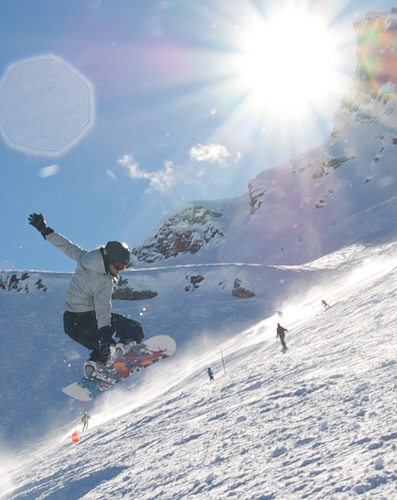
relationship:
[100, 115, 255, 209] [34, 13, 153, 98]
clouds in sky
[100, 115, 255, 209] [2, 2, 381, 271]
clouds in sky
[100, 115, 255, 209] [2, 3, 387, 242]
clouds in sky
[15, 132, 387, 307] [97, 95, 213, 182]
mountain with clouds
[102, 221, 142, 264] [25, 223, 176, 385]
helmet on snowboarder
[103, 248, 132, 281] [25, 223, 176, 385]
goggles on snowboarder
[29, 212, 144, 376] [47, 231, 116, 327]
person wearing coat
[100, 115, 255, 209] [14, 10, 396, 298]
clouds in sky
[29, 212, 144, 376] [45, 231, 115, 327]
person has jacket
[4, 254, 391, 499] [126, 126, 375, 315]
snow on mountain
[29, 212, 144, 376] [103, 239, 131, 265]
person wearing helmet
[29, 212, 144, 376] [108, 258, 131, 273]
person has goggles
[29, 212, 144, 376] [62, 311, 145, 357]
person has pants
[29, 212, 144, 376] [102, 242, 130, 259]
person wearing helmet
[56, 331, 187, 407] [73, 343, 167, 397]
board has designs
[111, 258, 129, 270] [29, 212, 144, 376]
goggles on person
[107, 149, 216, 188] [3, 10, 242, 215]
clouds in sky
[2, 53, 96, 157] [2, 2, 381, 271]
lens flare in sky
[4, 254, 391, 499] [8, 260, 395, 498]
snow on hill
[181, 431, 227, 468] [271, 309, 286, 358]
snow on people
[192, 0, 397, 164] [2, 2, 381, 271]
glares in sky